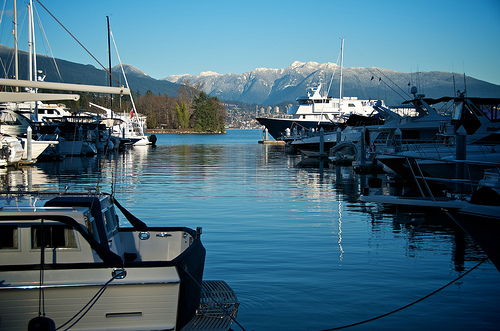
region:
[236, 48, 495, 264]
boats on the water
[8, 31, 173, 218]
boats on the water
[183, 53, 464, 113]
mountains in the distance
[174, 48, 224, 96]
This is a hill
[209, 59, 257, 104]
This is a hill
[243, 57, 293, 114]
This is a hill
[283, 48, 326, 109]
This is a hill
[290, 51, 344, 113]
This is a hill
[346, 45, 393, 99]
This is a hill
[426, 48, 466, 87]
This is a hill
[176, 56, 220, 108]
This is a hill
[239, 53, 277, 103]
This is a hill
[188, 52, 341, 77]
snow capped mountains in the distance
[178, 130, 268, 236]
water is calm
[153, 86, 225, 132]
trees growing on land beyond the boats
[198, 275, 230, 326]
small back deck on the boat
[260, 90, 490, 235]
boats all docked together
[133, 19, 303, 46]
bright blue sky above the mountains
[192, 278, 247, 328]
rope going down from the boat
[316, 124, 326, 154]
post on the dock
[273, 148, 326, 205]
reflection on the water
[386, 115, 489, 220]
boats sitting in shade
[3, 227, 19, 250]
glass window on boat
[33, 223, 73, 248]
glass window on boat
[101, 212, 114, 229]
glass window on boat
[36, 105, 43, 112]
glass window on boat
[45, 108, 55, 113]
glass window on boat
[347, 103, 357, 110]
glass window on boat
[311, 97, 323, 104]
glass window on boat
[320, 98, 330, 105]
glass window on boat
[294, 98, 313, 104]
glass window on boat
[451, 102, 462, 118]
glass window on boat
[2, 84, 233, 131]
a row of green trees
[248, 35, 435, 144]
a large blue and white boat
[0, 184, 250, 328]
a white boat parked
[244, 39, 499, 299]
a row of parked boats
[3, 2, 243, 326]
a row of parked boats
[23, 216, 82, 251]
a window on a boat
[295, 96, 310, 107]
a window on a boat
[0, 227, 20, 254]
a window on a boat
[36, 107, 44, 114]
a window on a boat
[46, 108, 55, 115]
a window on a boat